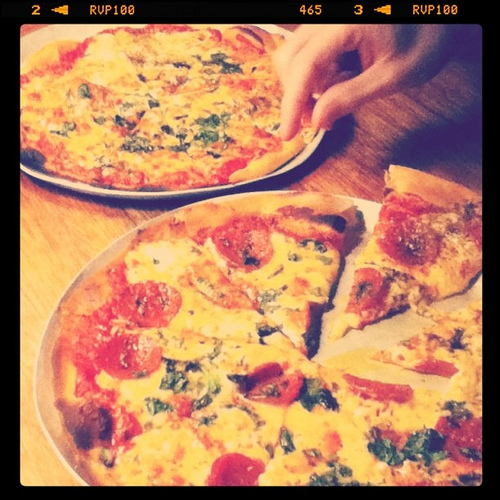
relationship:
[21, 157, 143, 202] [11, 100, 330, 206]
edge of plate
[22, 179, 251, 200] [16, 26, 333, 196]
edge of plate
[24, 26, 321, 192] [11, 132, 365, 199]
pizza on a plate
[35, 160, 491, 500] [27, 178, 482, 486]
pizza on a pizza plate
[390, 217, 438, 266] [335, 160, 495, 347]
pepperoni on a pizza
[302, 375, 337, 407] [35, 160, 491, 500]
parsley on a pizza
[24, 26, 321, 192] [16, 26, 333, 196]
pizza on a plate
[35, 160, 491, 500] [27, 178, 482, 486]
pizza on pizza plate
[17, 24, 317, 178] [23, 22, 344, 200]
pizza on dish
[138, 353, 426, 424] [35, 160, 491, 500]
garnishments on pizza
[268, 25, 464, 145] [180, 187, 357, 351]
hand reaching for slice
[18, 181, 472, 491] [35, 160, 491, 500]
crust on pizza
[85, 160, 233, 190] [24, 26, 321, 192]
sauce on pizza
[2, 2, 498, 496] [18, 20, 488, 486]
border around picture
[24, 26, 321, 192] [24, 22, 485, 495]
pizza on table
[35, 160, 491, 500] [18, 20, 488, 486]
pizza at bottom of picture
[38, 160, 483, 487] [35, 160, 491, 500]
pizza cut from pizza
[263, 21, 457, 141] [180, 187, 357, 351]
person reaching for slice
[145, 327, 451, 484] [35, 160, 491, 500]
spinach on top of pizza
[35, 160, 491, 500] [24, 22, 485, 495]
pizza on top of table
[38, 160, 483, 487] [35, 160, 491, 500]
pizza of pizza